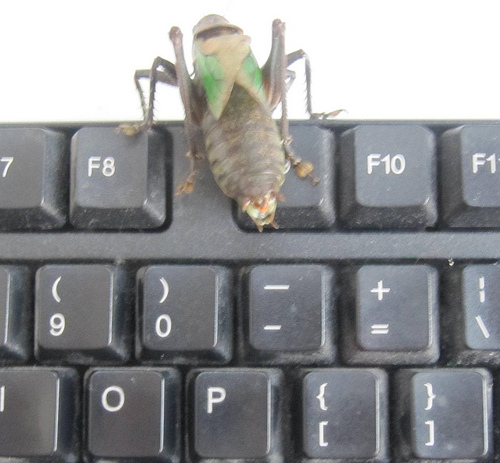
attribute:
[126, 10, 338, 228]
bug — creepy, unwanted, greenback, crawling, ugly, brown, green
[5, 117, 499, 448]
keyboard — computer, black, dirty, dusty, typewriter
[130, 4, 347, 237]
insect — ugly, greenbacked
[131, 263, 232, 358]
key — bracket, o, dirty, black, plastic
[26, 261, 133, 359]
key — bracket, plastic, 9, dirty, black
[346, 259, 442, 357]
key — equal sign, dirty, +, plastic, black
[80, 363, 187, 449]
o — letter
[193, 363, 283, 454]
p — letter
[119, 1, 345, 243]
grasshopper — standing, crawling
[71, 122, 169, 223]
f8 — number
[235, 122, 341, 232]
f9 — number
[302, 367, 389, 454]
key — bracket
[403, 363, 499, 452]
key — bracket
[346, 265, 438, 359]
sign — equal, plus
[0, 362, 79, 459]
key — letter, barely visible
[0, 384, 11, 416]
letter — i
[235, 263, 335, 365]
key — underscore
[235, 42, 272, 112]
wing — green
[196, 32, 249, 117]
wing — green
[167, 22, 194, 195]
leg — long, brown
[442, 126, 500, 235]
key — number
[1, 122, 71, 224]
key — number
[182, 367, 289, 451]
key — black, plastic, dirty, p, computer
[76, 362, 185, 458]
key — o, black, plastic, dirty, computer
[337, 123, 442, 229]
f10 — plastic, dirty, black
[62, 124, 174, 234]
key — dirty, black, plastic, f8